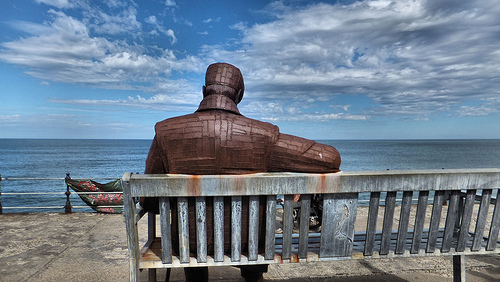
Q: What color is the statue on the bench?
A: Brown.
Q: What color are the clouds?
A: White.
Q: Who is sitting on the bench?
A: Statue.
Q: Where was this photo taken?
A: Ocean.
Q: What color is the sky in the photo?
A: Blue.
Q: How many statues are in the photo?
A: One.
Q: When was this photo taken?
A: Daytime.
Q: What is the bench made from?
A: Wood.